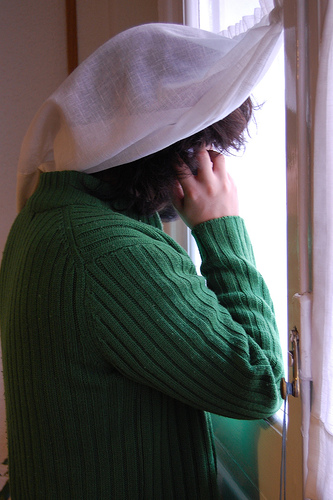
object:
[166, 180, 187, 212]
thumb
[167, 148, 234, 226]
hand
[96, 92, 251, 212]
hair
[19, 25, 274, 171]
curtain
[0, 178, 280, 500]
sweater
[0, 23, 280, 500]
woman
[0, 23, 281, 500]
man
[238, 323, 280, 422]
elbow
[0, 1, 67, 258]
wall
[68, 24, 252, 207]
head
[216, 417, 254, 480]
shadow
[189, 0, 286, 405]
window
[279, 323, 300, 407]
handle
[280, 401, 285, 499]
ribbon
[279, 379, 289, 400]
knob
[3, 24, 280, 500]
person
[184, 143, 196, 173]
phone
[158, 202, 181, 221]
beard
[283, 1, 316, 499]
door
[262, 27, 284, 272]
light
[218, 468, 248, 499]
baseboard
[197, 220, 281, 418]
sleeve